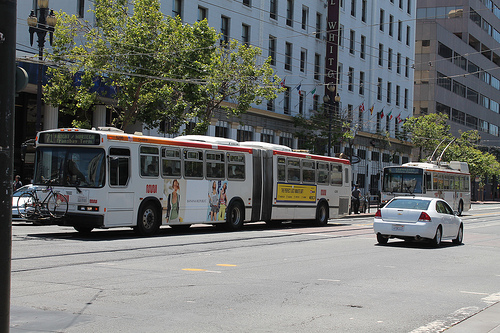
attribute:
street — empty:
[181, 202, 498, 333]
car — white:
[373, 194, 468, 248]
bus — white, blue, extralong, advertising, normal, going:
[33, 128, 351, 232]